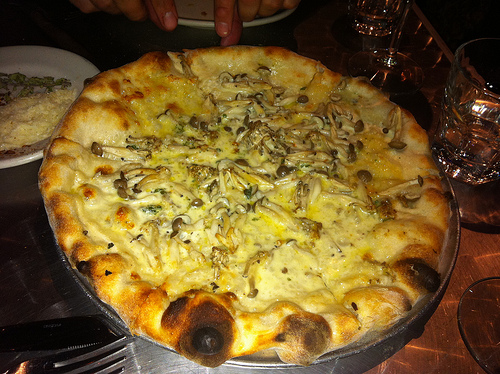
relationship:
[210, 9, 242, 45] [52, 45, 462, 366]
finger touching pan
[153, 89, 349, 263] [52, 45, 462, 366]
mushrooms on top of pan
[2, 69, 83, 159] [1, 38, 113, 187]
food on plate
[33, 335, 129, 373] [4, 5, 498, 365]
fork on countertop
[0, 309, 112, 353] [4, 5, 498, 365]
butter knife on countertop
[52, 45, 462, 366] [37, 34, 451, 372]
pan in pan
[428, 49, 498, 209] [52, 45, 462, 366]
glass next to pan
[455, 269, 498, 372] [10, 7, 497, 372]
plate on table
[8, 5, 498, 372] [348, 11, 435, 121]
wine glass on table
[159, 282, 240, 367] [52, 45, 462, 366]
burnt spot on pan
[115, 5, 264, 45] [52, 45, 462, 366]
fingers going to grab pan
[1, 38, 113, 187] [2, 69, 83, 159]
plate filled with food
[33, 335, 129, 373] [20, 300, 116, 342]
fork with knife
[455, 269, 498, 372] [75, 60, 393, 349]
plate with pizza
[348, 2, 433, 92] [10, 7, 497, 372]
glass on top of table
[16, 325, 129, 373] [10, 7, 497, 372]
fork on top of table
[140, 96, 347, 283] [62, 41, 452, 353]
cheese on top of pizza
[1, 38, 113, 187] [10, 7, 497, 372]
plate on top of table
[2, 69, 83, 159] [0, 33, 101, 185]
food on plate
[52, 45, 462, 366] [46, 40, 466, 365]
pan on platter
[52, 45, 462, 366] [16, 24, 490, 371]
pan on platter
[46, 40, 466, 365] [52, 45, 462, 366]
platter with pan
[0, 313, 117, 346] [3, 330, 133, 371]
butter knife beside fork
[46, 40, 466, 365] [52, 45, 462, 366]
platter holding pan